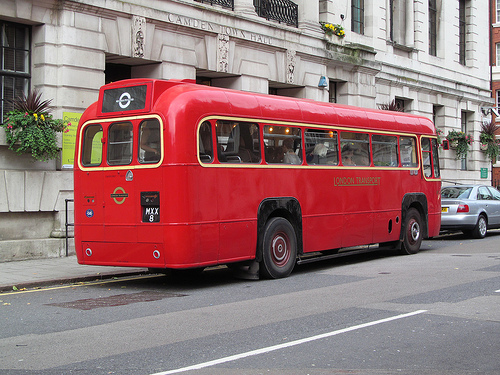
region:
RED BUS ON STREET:
[53, 68, 466, 294]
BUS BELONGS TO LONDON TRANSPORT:
[308, 156, 409, 217]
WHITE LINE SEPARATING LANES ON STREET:
[134, 288, 448, 372]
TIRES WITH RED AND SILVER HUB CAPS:
[238, 198, 456, 281]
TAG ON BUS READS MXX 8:
[123, 180, 181, 242]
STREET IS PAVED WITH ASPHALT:
[19, 283, 490, 370]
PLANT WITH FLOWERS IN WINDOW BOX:
[3, 86, 86, 183]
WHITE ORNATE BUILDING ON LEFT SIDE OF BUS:
[19, 0, 489, 211]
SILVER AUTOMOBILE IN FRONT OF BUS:
[436, 180, 496, 240]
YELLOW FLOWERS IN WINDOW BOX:
[303, 7, 387, 51]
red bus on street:
[74, 73, 443, 268]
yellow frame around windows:
[70, 120, 196, 195]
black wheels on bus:
[249, 214, 308, 276]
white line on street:
[283, 298, 414, 373]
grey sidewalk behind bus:
[8, 234, 122, 284]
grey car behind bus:
[442, 187, 497, 246]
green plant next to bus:
[4, 99, 94, 184]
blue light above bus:
[299, 64, 325, 94]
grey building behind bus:
[38, 0, 491, 173]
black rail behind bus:
[52, 188, 73, 264]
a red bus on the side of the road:
[59, 68, 474, 302]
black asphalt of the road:
[163, 272, 315, 317]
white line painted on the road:
[284, 305, 395, 368]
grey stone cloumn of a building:
[45, 32, 91, 94]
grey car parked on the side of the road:
[433, 170, 495, 245]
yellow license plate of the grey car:
[442, 204, 452, 214]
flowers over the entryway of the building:
[318, 18, 349, 38]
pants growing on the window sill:
[3, 97, 60, 151]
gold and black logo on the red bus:
[103, 185, 133, 205]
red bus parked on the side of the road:
[73, 66, 478, 271]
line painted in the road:
[293, 293, 434, 344]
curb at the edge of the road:
[16, 277, 85, 297]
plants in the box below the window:
[5, 93, 60, 167]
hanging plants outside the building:
[431, 110, 471, 161]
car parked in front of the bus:
[444, 160, 498, 233]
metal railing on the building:
[256, 0, 304, 23]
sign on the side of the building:
[63, 108, 103, 179]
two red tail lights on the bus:
[76, 240, 171, 270]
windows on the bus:
[213, 123, 425, 169]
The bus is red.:
[81, 78, 442, 268]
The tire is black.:
[250, 213, 309, 276]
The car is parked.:
[438, 180, 498, 232]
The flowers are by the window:
[4, 95, 69, 158]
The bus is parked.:
[82, 77, 447, 274]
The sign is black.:
[101, 85, 156, 114]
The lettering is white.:
[108, 88, 139, 114]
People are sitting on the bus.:
[206, 119, 422, 171]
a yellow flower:
[323, 20, 333, 30]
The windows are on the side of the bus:
[189, 103, 447, 170]